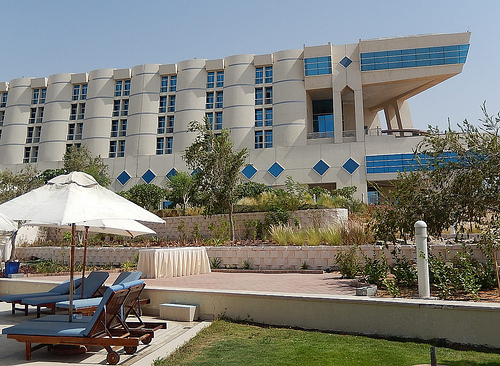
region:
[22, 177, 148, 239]
white umbrellas above chairs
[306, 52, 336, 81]
blue window on building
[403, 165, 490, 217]
green trees in front of building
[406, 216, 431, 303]
white post on ground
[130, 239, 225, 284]
tablecloth on table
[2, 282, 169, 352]
blue and brown chairs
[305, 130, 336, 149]
deck on building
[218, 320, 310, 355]
green grass on the ground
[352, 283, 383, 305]
cement block on the ground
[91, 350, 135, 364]
wheel on the chair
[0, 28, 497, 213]
white hotel building with blue mirrored windows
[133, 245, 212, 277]
catering table with white tablecloth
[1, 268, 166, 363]
pool chase lounges with blue padding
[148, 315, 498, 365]
patch of grass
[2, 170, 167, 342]
large white pool umbrellas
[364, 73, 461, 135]
hotel balcony with chairs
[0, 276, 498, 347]
very short cement wall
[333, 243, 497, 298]
small shrubs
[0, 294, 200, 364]
tiled pool deck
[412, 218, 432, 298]
white baricade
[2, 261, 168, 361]
A group of blue reclining chairs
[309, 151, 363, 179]
Two blue diamond designs on a building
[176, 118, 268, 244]
A tree with green leaves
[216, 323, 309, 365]
A green grass ground surface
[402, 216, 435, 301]
A white pole with a light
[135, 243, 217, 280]
A buffet table with a white curtain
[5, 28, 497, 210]
A building with blue windows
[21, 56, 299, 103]
A group of windows on a white building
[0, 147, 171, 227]
A white patio umbrella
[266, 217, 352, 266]
Tall grass growing above a wall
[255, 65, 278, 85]
black window in tan building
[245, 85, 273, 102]
black window in tan building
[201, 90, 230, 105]
black window in tan building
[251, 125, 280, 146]
black window in tan building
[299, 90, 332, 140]
black window in tan building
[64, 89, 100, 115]
black window in tan building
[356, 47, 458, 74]
black window in tan building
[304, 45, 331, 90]
black window in tan building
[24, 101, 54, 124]
black window in tan building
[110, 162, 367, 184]
Blue diamonds on side of building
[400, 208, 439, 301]
White post in the planter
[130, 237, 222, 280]
The table cloth is white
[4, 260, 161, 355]
The chair cushions are blue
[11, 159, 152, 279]
The umbrellas are white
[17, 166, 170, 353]
Umbrellas over the chairs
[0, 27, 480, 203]
The building windows are blue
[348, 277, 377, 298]
Green box in the planter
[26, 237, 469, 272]
Low, tan block wall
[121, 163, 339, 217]
Bushes and trees in front of the building